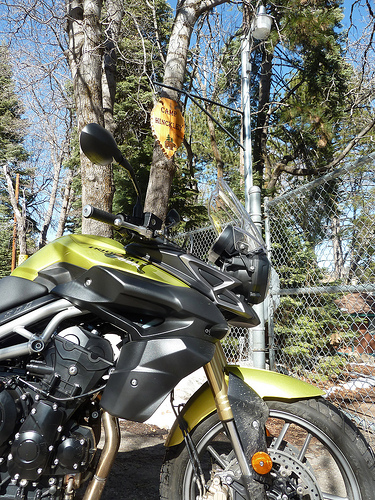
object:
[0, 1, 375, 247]
sky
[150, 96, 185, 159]
sign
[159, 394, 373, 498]
wheel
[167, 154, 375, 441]
fence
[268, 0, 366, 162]
leaves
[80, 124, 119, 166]
mirror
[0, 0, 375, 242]
trees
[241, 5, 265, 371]
lamp post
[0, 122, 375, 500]
motorcycle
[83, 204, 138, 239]
handle bar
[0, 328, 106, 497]
engine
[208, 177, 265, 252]
windshield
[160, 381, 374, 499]
tire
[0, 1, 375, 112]
clouds